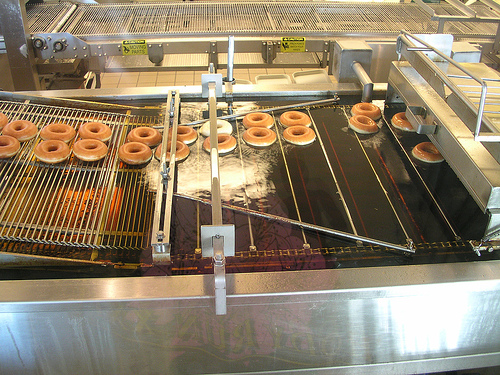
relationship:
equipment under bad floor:
[25, 4, 466, 74] [90, 64, 207, 84]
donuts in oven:
[163, 97, 455, 241] [27, 39, 407, 317]